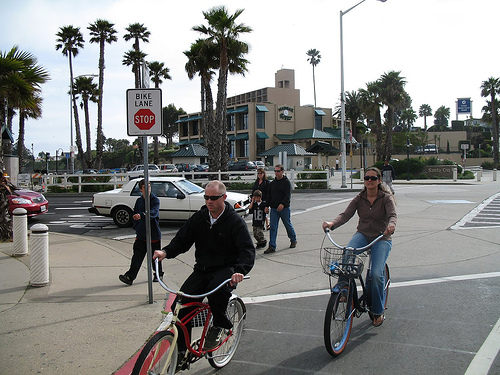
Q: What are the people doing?
A: Riding bikes.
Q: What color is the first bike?
A: Red.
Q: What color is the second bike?
A: Blue.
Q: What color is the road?
A: Gray.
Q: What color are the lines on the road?
A: White.